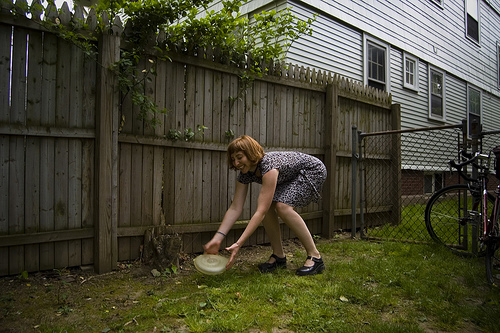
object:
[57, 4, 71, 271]
wood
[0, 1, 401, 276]
fence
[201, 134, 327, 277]
woman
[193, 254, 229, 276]
frisbee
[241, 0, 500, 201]
house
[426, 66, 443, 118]
window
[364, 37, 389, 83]
window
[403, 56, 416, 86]
window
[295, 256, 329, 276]
left foot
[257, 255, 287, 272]
right foot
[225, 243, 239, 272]
left hand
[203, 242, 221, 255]
right hand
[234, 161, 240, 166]
nose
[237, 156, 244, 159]
left eye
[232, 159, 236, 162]
right eye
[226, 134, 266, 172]
hair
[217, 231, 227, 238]
bracelet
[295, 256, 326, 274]
shoe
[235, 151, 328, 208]
dress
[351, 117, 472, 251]
gate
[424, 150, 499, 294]
bike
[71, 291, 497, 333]
grass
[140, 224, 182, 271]
back pack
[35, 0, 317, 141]
tree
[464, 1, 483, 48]
window